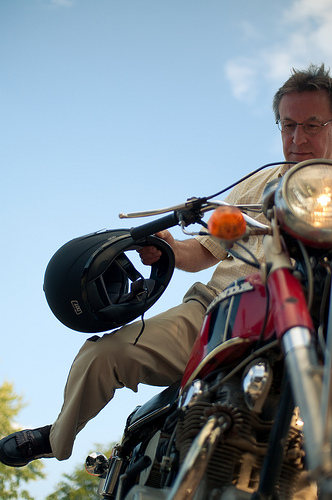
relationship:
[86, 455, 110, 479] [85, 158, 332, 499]
rear light on bike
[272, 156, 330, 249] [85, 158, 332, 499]
front light on bike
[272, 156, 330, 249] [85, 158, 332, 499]
front light on a bike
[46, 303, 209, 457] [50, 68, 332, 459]
leg of a man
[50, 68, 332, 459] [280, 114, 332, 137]
man wears glasses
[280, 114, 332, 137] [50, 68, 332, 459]
glasses on a man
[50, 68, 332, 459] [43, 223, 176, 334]
man holds a helmet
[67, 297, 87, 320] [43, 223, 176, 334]
logo on helmet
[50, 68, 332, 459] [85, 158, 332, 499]
man getting off bike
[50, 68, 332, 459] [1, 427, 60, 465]
man wears black shoe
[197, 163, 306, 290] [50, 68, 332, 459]
shirt on man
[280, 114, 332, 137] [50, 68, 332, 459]
glasses on man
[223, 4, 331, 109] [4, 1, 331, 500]
clouds in sky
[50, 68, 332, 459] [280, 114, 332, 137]
man wearing glasses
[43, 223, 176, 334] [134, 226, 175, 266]
helmet in mans hand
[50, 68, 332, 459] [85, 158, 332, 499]
man getting on a bike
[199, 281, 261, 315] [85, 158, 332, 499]
maker of bike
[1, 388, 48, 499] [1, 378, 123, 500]
tree with leaves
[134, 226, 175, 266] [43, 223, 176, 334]
hand holding helmet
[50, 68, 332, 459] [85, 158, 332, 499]
man climbs on bike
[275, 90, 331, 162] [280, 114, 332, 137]
face wearing glasses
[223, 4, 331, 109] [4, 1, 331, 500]
clouds float through sky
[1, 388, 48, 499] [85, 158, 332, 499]
tree behind bike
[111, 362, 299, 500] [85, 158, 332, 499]
motor on bike